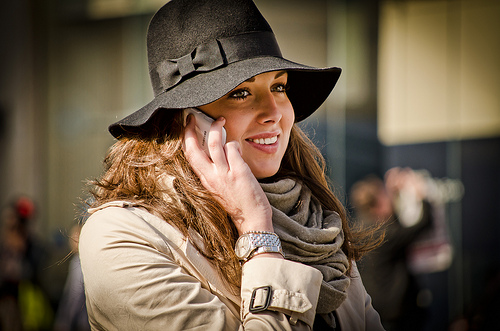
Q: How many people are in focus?
A: One.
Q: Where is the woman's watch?
A: Wrist.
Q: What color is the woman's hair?
A: Brown.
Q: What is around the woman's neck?
A: Scarf.